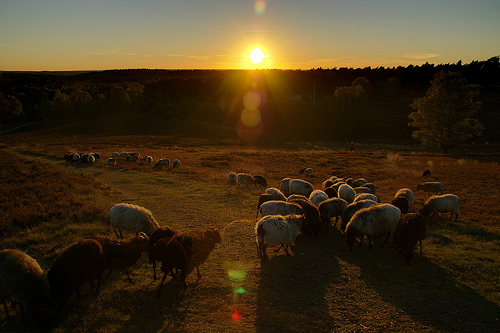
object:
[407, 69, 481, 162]
green tree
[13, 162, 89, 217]
brown/green grasses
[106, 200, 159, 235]
white sheep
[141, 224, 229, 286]
brown sheep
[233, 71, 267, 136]
sunlight reflection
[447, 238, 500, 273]
short/green grass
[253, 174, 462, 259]
sheep herd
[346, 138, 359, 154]
man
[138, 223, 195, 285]
sheep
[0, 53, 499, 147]
mountains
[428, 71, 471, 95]
tree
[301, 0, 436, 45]
sky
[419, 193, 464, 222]
sheep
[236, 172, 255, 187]
sheep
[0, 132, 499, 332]
field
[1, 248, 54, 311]
sheep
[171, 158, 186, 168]
sheep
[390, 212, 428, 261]
sheep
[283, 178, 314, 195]
sheep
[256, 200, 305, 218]
sheep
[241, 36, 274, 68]
sun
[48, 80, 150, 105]
trees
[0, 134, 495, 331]
pasture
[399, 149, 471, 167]
bush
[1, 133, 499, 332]
path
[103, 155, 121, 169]
sheep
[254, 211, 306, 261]
sheep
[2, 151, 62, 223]
grass